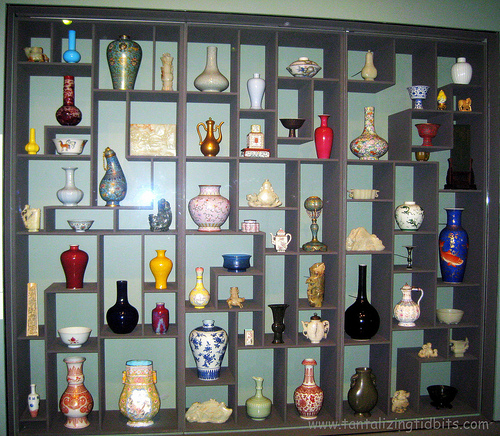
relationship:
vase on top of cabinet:
[313, 111, 336, 162] [2, 3, 498, 435]